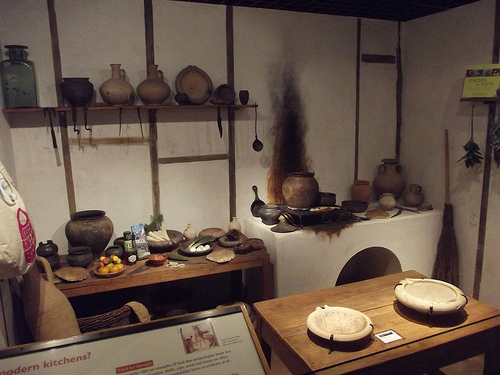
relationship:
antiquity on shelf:
[59, 77, 94, 107] [19, 105, 258, 121]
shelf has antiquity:
[19, 105, 258, 121] [59, 77, 94, 107]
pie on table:
[389, 259, 465, 317] [226, 276, 485, 349]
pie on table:
[306, 289, 358, 357] [226, 276, 485, 349]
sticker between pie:
[376, 320, 398, 359] [393, 277, 465, 317]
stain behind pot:
[272, 94, 312, 169] [266, 155, 327, 221]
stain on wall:
[272, 94, 312, 169] [253, 17, 352, 158]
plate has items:
[89, 273, 116, 284] [94, 245, 123, 271]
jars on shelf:
[60, 63, 240, 107] [19, 105, 258, 121]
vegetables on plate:
[94, 251, 118, 280] [89, 273, 116, 284]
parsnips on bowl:
[136, 202, 172, 238] [147, 235, 183, 252]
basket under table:
[82, 287, 142, 340] [21, 241, 257, 336]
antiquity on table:
[64, 209, 114, 258] [21, 241, 257, 336]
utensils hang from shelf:
[42, 108, 268, 158] [19, 105, 258, 121]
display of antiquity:
[5, 9, 281, 303] [50, 201, 118, 255]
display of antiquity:
[5, 9, 281, 303] [213, 212, 252, 248]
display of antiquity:
[5, 9, 281, 303] [43, 69, 100, 109]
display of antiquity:
[5, 9, 281, 303] [80, 249, 130, 273]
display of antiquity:
[5, 9, 281, 303] [7, 39, 40, 114]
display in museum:
[5, 9, 281, 303] [8, 11, 488, 364]